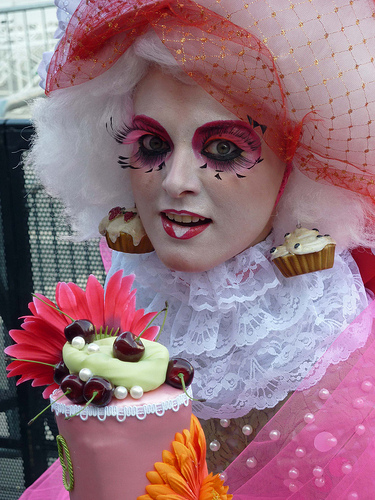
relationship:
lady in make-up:
[17, 0, 374, 499] [188, 119, 266, 180]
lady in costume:
[17, 0, 374, 499] [111, 244, 363, 488]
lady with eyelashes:
[17, 0, 374, 499] [106, 110, 275, 182]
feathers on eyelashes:
[117, 153, 163, 174] [106, 110, 275, 182]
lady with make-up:
[17, 0, 374, 499] [188, 111, 262, 192]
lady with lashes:
[17, 0, 374, 499] [113, 116, 169, 165]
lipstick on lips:
[166, 224, 198, 234] [149, 202, 214, 247]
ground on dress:
[271, 99, 307, 126] [189, 262, 361, 479]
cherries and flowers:
[6, 290, 205, 425] [1, 262, 226, 496]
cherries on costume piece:
[6, 290, 205, 425] [3, 267, 231, 497]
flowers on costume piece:
[1, 262, 226, 496] [3, 267, 231, 497]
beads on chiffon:
[94, 77, 254, 230] [278, 408, 352, 493]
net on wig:
[44, 0, 374, 197] [33, 81, 127, 232]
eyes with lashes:
[123, 118, 248, 181] [199, 115, 267, 182]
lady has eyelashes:
[46, 18, 371, 428] [122, 118, 274, 181]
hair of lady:
[33, 80, 165, 237] [17, 0, 374, 499]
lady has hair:
[17, 0, 374, 499] [33, 80, 165, 237]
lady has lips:
[31, 1, 343, 410] [156, 223, 209, 239]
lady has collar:
[17, 0, 374, 499] [102, 229, 373, 420]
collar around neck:
[102, 229, 373, 420] [142, 247, 329, 367]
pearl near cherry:
[128, 383, 147, 398] [171, 356, 191, 385]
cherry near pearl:
[171, 356, 191, 385] [128, 383, 147, 398]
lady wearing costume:
[17, 0, 374, 499] [1, 0, 373, 499]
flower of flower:
[139, 415, 235, 500] [139, 411, 230, 498]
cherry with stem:
[113, 307, 166, 362] [129, 304, 168, 342]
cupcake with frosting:
[269, 224, 336, 278] [265, 225, 306, 268]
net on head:
[45, 0, 373, 201] [121, 71, 266, 258]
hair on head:
[12, 0, 375, 256] [118, 60, 286, 268]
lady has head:
[17, 0, 374, 499] [118, 60, 286, 268]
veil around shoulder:
[241, 415, 335, 480] [307, 296, 370, 357]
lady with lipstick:
[17, 0, 374, 499] [165, 221, 204, 239]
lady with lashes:
[17, 0, 374, 499] [105, 116, 170, 174]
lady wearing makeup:
[17, 0, 374, 499] [127, 111, 253, 240]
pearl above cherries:
[78, 367, 93, 382] [61, 372, 112, 406]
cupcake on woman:
[268, 223, 335, 278] [67, 0, 373, 271]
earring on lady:
[98, 204, 155, 255] [17, 0, 374, 499]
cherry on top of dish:
[107, 324, 152, 360] [51, 363, 175, 472]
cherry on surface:
[167, 358, 205, 402] [145, 391, 194, 403]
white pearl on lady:
[240, 422, 252, 435] [17, 0, 374, 499]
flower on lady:
[139, 415, 235, 500] [17, 0, 374, 499]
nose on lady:
[160, 140, 200, 198] [17, 0, 374, 499]